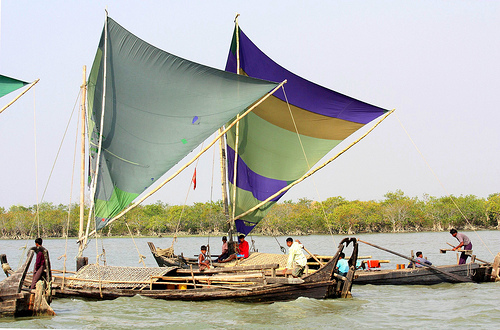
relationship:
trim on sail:
[223, 30, 386, 127] [214, 16, 400, 264]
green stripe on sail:
[207, 108, 364, 188] [206, 32, 361, 259]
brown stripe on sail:
[231, 65, 353, 162] [208, 16, 389, 251]